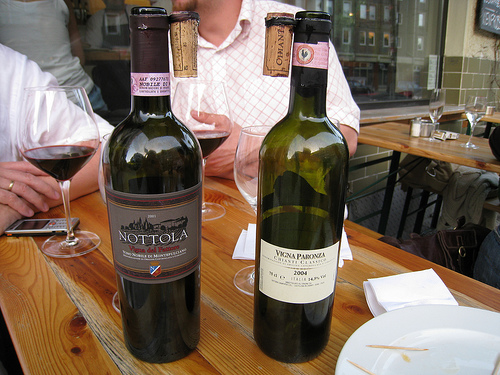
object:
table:
[1, 172, 500, 373]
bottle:
[250, 7, 350, 364]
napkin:
[357, 265, 459, 318]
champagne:
[253, 8, 351, 363]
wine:
[102, 14, 204, 361]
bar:
[0, 102, 499, 374]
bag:
[433, 227, 482, 277]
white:
[335, 304, 498, 374]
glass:
[231, 125, 267, 295]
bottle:
[100, 5, 209, 365]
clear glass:
[16, 83, 101, 258]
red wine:
[18, 146, 99, 180]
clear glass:
[460, 90, 489, 150]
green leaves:
[425, 85, 450, 142]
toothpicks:
[345, 343, 437, 374]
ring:
[6, 180, 20, 190]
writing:
[109, 229, 200, 260]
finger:
[0, 190, 35, 219]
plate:
[333, 303, 500, 375]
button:
[47, 216, 69, 232]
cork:
[262, 11, 298, 78]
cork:
[168, 13, 198, 77]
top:
[280, 0, 342, 38]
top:
[119, 5, 167, 37]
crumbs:
[397, 350, 414, 365]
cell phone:
[4, 216, 81, 236]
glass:
[427, 84, 445, 144]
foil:
[122, 5, 171, 106]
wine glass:
[422, 85, 444, 136]